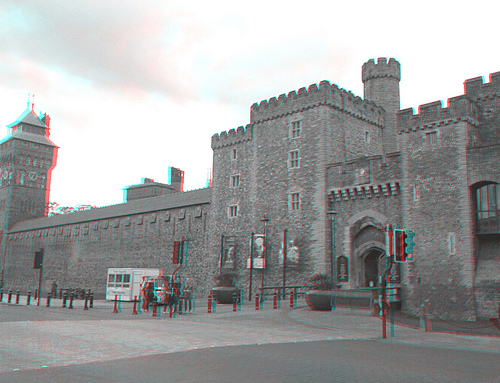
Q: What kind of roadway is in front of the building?
A: Paved and stone.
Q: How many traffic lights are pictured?
A: Three.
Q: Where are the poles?
A: By the building.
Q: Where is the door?
A: On the building.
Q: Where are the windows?
A: On the building.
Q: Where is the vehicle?
A: By the building.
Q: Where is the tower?
A: On the building.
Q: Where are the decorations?
A: On the wall.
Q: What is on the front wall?
A: Six windows.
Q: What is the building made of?
A: Gray brick.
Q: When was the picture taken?
A: Daytime.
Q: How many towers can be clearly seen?
A: 2.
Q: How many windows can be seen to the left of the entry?
A: 6.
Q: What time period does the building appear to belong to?
A: Medieval times.